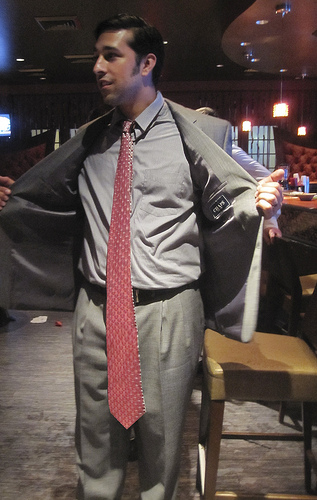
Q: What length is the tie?
A: Super long.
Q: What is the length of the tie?
A: Super long.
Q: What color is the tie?
A: Red.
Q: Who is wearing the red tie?
A: A person.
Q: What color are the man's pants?
A: Gray.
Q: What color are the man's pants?
A: Gray.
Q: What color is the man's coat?
A: Gray.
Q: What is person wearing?
A: Belt.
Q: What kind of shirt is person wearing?
A: Collared.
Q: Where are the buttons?
A: On shirt.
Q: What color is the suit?
A: Gray.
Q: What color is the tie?
A: Red.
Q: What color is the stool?
A: Yellow.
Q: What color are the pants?
A: Gray.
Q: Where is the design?
A: On tie.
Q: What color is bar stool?
A: Brown.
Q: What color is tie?
A: Pink.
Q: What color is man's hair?
A: Brown.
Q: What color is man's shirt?
A: Gray.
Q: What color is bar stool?
A: Beige.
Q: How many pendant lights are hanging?
A: Three.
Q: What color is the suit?
A: Gray.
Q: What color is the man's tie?
A: Red.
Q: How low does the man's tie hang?
A: To his knees.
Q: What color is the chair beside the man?
A: Yellow.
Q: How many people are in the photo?
A: 2.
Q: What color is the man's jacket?
A: Gray.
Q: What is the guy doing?
A: Showing off his tie.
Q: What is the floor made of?
A: Wood.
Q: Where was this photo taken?
A: At a bar.